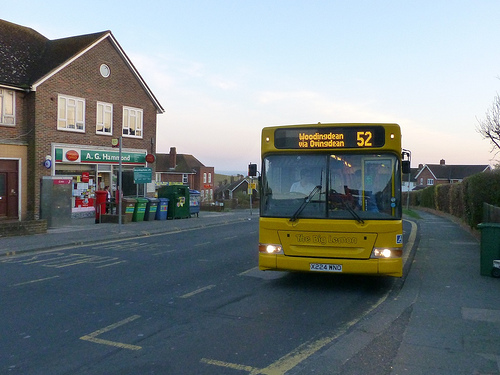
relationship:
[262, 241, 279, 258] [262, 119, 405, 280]
light on bus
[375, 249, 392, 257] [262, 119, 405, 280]
light on bus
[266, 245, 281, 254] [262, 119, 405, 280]
light on bus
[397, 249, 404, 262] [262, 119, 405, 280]
light on bus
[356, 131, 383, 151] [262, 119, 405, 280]
number on bus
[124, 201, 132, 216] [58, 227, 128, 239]
trash bin on sidewalk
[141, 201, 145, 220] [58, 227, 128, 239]
trash bin on sidewalk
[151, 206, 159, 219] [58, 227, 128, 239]
trash bin on sidewalk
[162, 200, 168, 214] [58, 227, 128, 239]
trash bin on sidewalk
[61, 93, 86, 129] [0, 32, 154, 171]
window on building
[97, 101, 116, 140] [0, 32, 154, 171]
window on building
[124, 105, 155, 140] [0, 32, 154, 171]
window on building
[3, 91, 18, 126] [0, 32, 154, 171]
window on building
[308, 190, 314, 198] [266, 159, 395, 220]
wiper on windshield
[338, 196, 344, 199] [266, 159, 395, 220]
wiper on windshield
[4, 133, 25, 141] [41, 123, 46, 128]
wall made of brick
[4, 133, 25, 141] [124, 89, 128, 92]
wall made of brick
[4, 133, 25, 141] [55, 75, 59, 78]
wall made of brick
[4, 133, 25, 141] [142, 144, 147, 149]
wall made of brick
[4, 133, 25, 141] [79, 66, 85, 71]
wall made of brick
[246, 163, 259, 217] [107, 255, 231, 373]
sign on road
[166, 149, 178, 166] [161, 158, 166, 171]
chimney on roof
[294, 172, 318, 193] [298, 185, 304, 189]
driver wearing shirt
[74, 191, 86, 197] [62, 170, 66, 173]
flyer on window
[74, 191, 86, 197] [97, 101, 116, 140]
flyer on window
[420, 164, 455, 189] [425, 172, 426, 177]
building made of brick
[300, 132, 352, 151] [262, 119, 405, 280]
name on bus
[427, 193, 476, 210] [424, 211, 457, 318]
hedge next to sidewalk